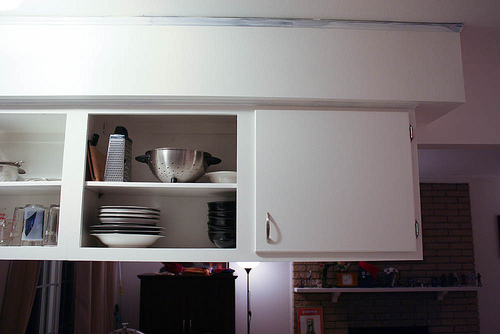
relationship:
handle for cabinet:
[265, 213, 271, 243] [237, 107, 425, 261]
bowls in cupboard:
[206, 201, 234, 247] [0, 107, 423, 261]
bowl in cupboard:
[205, 171, 236, 184] [0, 107, 423, 261]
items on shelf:
[87, 125, 236, 185] [85, 181, 236, 200]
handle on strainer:
[136, 154, 149, 163] [134, 146, 221, 183]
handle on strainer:
[205, 156, 221, 166] [134, 146, 221, 183]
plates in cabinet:
[87, 205, 166, 246] [0, 107, 423, 261]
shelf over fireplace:
[292, 285, 489, 302] [347, 327, 436, 334]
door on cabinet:
[253, 110, 417, 254] [237, 107, 425, 261]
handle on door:
[265, 213, 271, 243] [253, 110, 417, 254]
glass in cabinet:
[21, 203, 52, 245] [0, 107, 423, 261]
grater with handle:
[101, 127, 131, 181] [112, 125, 127, 135]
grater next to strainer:
[101, 127, 131, 181] [134, 146, 221, 183]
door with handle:
[253, 110, 417, 254] [265, 213, 271, 243]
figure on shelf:
[476, 272, 483, 286] [292, 285, 489, 302]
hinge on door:
[409, 123, 415, 141] [253, 110, 417, 254]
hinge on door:
[414, 221, 420, 238] [253, 110, 417, 254]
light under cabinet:
[236, 261, 258, 270] [237, 107, 425, 261]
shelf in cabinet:
[85, 181, 236, 200] [0, 107, 423, 261]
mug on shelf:
[9, 204, 44, 247] [0, 246, 56, 253]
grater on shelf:
[101, 127, 131, 181] [85, 181, 236, 200]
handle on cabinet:
[179, 318, 187, 333] [136, 273, 238, 333]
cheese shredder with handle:
[101, 127, 131, 181] [112, 125, 127, 135]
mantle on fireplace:
[292, 285, 489, 302] [347, 327, 436, 334]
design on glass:
[22, 206, 44, 241] [21, 203, 52, 245]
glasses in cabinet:
[0, 203, 60, 246] [0, 107, 423, 261]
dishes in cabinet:
[86, 202, 235, 246] [0, 107, 423, 261]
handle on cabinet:
[187, 319, 194, 331] [136, 273, 238, 333]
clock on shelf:
[337, 270, 358, 285] [292, 285, 489, 302]